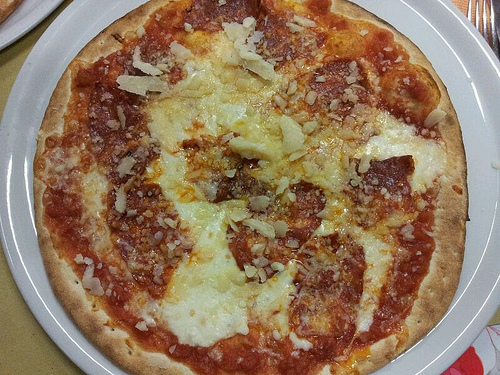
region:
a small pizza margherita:
[31, 0, 467, 374]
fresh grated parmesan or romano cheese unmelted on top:
[116, 15, 445, 347]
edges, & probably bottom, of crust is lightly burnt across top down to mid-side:
[32, 0, 479, 226]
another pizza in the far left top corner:
[0, 0, 27, 30]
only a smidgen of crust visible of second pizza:
[0, 0, 30, 26]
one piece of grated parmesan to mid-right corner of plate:
[486, 156, 498, 173]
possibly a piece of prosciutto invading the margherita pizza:
[337, 147, 421, 207]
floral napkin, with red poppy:
[424, 322, 499, 374]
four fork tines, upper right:
[459, 1, 498, 58]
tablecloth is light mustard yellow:
[0, 1, 499, 373]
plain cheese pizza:
[31, 1, 471, 373]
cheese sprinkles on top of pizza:
[116, 40, 221, 107]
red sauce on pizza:
[83, 78, 129, 147]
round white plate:
[0, 38, 495, 371]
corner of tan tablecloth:
[0, 255, 80, 367]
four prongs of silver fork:
[460, 0, 495, 57]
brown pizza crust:
[80, 31, 130, 56]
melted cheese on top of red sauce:
[35, 145, 85, 190]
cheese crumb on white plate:
[475, 151, 495, 176]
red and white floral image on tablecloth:
[440, 310, 497, 371]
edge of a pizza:
[453, 175, 463, 217]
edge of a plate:
[473, 295, 484, 325]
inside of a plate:
[471, 137, 480, 161]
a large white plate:
[463, 244, 481, 289]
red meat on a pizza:
[130, 217, 158, 271]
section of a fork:
[481, 7, 495, 28]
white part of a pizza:
[241, 234, 361, 305]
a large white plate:
[422, 320, 459, 360]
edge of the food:
[103, 322, 122, 352]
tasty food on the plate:
[198, 175, 340, 283]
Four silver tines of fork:
[455, 0, 499, 57]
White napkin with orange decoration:
[441, 312, 496, 373]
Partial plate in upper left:
[0, 0, 67, 47]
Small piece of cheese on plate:
[483, 151, 498, 176]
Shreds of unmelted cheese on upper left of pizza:
[101, 10, 285, 99]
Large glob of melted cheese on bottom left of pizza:
[153, 210, 253, 352]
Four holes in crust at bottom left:
[52, 265, 144, 365]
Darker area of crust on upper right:
[343, 0, 420, 35]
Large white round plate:
[1, 0, 498, 373]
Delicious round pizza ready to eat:
[30, 0, 469, 372]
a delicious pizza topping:
[75, 260, 112, 297]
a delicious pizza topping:
[242, 217, 282, 256]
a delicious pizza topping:
[110, 185, 129, 210]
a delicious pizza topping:
[220, 127, 271, 167]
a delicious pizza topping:
[277, 110, 314, 162]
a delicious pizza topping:
[117, 71, 168, 96]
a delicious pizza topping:
[241, 31, 278, 82]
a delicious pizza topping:
[414, 102, 447, 135]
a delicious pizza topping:
[221, 15, 256, 41]